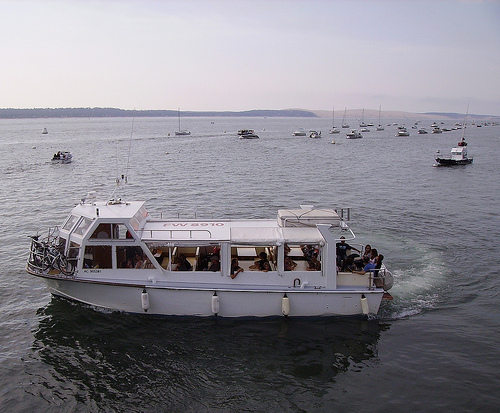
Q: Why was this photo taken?
A: To show the boat.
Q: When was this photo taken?
A: During the day.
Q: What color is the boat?
A: White.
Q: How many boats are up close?
A: 1.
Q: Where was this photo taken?
A: Outside on the water.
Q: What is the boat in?
A: The water.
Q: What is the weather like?
A: Cloudy.